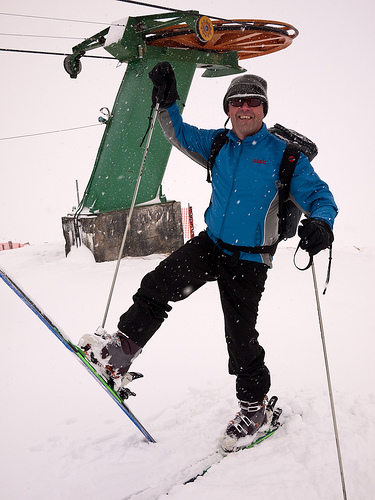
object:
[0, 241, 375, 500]
ground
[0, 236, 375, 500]
snow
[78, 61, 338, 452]
man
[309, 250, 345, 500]
ski pole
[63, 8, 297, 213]
ski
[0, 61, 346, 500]
skier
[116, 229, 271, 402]
pants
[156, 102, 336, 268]
jacket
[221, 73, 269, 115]
hat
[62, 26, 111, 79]
metal